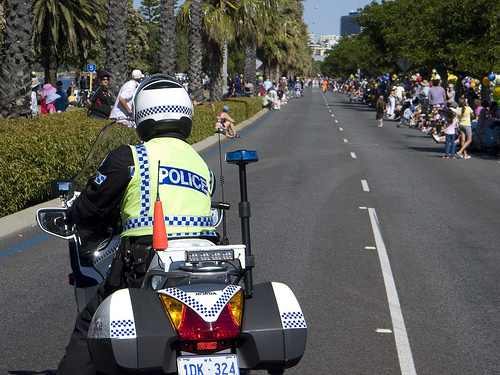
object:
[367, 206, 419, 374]
lines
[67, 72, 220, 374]
policeman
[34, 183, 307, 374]
bike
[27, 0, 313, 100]
palms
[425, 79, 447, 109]
spectators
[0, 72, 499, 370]
street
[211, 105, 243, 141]
people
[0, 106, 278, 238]
curb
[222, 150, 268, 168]
light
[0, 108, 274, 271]
line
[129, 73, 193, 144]
helmet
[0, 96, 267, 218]
bushes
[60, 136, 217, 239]
jacket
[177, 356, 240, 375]
license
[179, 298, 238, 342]
light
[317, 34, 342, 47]
buildings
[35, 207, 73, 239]
rearview mirror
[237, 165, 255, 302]
pole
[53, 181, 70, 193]
camera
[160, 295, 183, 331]
lights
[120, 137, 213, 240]
vest